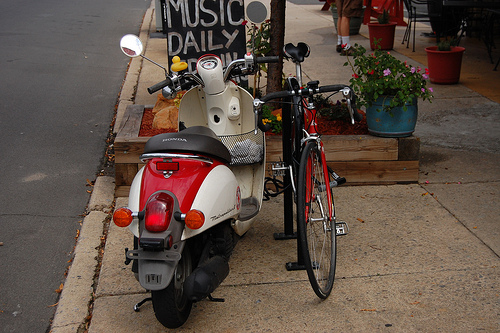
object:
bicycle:
[256, 41, 350, 299]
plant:
[340, 37, 433, 113]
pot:
[366, 98, 419, 139]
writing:
[162, 0, 246, 57]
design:
[234, 184, 242, 212]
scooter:
[113, 33, 279, 328]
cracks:
[415, 182, 500, 259]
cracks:
[97, 264, 500, 297]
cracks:
[420, 93, 485, 101]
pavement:
[49, 1, 499, 332]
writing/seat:
[144, 125, 234, 163]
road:
[0, 0, 500, 332]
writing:
[160, 136, 190, 142]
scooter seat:
[141, 124, 233, 167]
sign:
[160, 0, 249, 88]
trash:
[107, 154, 115, 161]